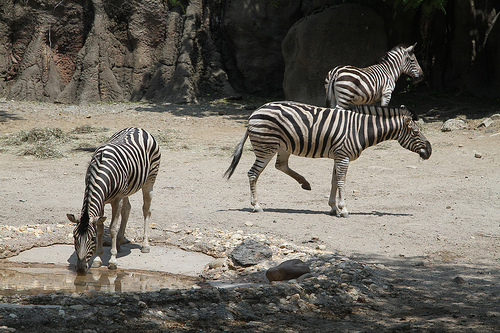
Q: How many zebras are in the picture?
A: Three.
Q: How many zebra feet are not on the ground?
A: One.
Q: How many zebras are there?
A: Three.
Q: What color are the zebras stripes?
A: Black and white.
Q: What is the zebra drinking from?
A: Puddle.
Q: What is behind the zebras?
A: Rocks.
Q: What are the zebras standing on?
A: Gravel.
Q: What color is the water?
A: Brown.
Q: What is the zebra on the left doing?
A: Drinking water.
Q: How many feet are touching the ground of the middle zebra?
A: Three.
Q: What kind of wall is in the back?
A: Rock.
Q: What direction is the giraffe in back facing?
A: Right.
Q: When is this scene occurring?
A: Mid afternoon.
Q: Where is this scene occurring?
A: Africa.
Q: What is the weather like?
A: Warm and sunny.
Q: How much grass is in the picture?
A: None.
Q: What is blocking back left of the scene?
A: Rock wall.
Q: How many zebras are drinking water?
A: 1.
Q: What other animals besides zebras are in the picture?
A: None.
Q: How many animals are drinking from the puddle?
A: One.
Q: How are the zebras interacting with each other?
A: They are not.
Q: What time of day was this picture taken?
A: In the Afternoon.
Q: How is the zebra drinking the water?
A: Mouth.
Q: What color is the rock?
A: Grey.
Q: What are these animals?
A: Zebras.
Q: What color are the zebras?
A: White and black.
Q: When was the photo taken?
A: During the day.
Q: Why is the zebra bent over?
A: It's drinking water.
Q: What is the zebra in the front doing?
A: Drinking water.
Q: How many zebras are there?
A: Three.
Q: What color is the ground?
A: Brown.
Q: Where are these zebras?
A: In a zoo.